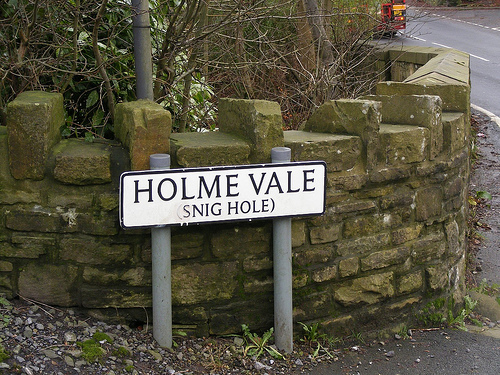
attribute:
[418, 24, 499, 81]
lines — white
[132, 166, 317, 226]
writing — color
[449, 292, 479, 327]
grass — weed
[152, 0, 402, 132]
tree branches — bunch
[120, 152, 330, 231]
steel plate — white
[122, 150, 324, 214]
plate — white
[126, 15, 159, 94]
pipe — steel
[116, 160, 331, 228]
sign — white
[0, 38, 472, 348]
wall — brown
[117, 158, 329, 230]
traffic sign — white, steel, plate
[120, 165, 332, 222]
sign — street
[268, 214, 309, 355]
pole — steel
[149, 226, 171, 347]
pole — steel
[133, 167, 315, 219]
writing — black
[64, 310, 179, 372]
moss — green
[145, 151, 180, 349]
pole — steel